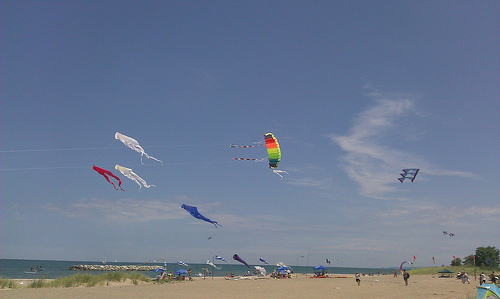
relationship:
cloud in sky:
[322, 80, 481, 199] [0, 0, 498, 269]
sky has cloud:
[0, 0, 498, 269] [322, 80, 481, 199]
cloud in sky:
[39, 193, 257, 235] [0, 0, 498, 269]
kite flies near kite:
[229, 133, 289, 179] [180, 204, 223, 230]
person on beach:
[355, 272, 362, 287] [2, 274, 499, 299]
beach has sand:
[2, 274, 499, 299] [49, 290, 136, 297]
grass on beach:
[1, 267, 185, 290] [2, 274, 499, 299]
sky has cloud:
[0, 0, 498, 269] [39, 193, 257, 235]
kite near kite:
[114, 164, 157, 191] [93, 164, 122, 192]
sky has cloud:
[0, 0, 498, 269] [374, 199, 499, 241]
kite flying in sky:
[398, 168, 419, 183] [0, 0, 498, 269]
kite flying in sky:
[229, 133, 289, 179] [0, 0, 498, 269]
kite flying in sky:
[93, 164, 122, 192] [0, 0, 498, 269]